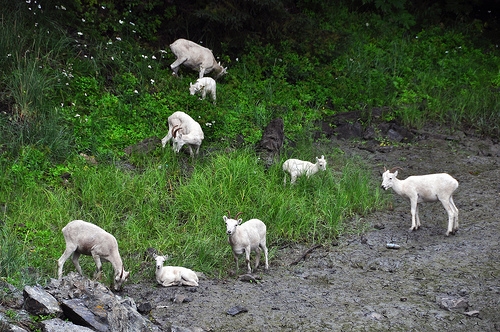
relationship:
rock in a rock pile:
[21, 281, 59, 319] [18, 268, 158, 329]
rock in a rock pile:
[38, 316, 97, 332] [18, 268, 158, 329]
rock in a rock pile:
[54, 268, 156, 330] [18, 268, 158, 329]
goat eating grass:
[166, 39, 230, 80] [3, 0, 498, 284]